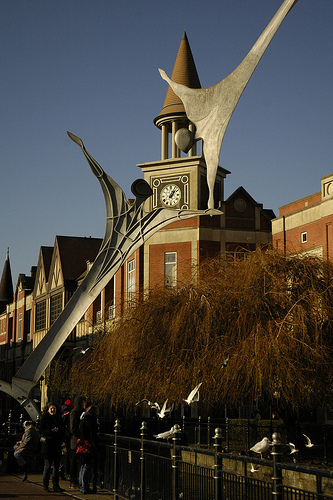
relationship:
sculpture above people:
[0, 0, 294, 428] [37, 427, 182, 480]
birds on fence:
[125, 375, 170, 413] [225, 442, 291, 487]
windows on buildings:
[90, 245, 208, 311] [23, 238, 280, 377]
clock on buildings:
[155, 186, 184, 210] [23, 238, 280, 377]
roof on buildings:
[274, 199, 313, 221] [23, 238, 280, 377]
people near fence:
[37, 427, 182, 480] [225, 442, 291, 487]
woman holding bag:
[62, 396, 116, 488] [68, 440, 95, 450]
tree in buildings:
[229, 293, 291, 331] [23, 238, 280, 377]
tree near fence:
[229, 293, 291, 331] [225, 442, 291, 487]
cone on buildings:
[186, 31, 224, 124] [23, 238, 280, 377]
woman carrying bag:
[62, 396, 116, 488] [68, 440, 95, 450]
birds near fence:
[125, 375, 170, 413] [225, 442, 291, 487]